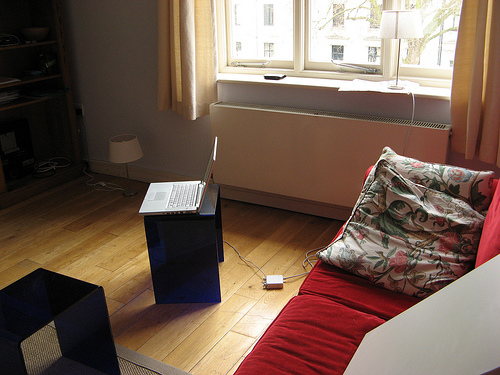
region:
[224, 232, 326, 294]
A computer charger.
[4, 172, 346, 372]
Brown hardwood floors.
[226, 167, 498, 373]
A red sofa.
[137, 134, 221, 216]
A laptop computer.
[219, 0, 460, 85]
White framed windows.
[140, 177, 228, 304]
A small dark colored table.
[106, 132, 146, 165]
A white lamp shade.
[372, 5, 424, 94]
A table lamp.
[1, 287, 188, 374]
A beige rug.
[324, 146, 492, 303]
Two beige pillows on the sofa with a floral design.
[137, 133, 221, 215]
Laptop on top of black table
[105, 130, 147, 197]
Lamp on wooden floor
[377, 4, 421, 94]
Small lamp next to window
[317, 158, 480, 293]
Pillow on red sofa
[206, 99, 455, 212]
Large heater below window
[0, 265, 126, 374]
Black stool on top of rug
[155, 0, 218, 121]
Curtain next to window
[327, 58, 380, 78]
Silver lever on window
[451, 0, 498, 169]
Curtain next to window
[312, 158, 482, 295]
Pillow leaning on pillow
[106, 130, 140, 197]
a small lmap on the floor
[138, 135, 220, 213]
silver laptop computer on a small stool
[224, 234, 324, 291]
power cord for the laptop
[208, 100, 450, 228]
radiator on the wall under the window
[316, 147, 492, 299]
floral pillows on the couch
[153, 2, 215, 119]
drapes to the left of the window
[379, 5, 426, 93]
small lamp on the windowsill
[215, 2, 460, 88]
three open bay windows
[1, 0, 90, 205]
entertainment center in the corner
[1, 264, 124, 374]
small empty blue table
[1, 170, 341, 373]
The floor is made of wood.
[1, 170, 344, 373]
The floor is brown.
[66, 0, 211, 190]
The wall is off white.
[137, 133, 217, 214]
A laptop.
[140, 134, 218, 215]
The laptop is gray.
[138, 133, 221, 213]
The laptop is open.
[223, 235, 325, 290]
A power cord.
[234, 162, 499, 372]
The couch is red.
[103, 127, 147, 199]
A lamp is on the floor.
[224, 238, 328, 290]
The power cord is white.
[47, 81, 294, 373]
a laptop on a table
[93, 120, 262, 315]
a silver laptop on a table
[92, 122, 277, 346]
a table with a laptop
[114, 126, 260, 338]
a table with silver laptop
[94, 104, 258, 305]
a table with a open laptop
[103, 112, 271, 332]
a laptop on top of a blue table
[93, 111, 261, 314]
a laptop on top of table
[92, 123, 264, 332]
a blue table on the floor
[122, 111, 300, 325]
a blue table with a laptop